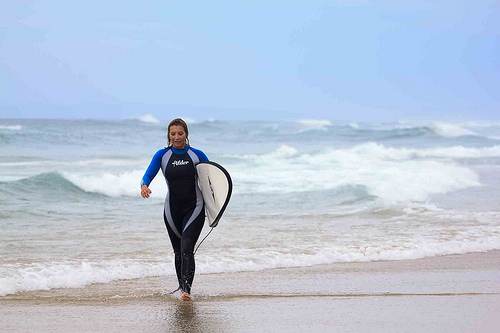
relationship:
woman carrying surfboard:
[140, 117, 209, 301] [192, 154, 233, 228]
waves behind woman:
[219, 108, 476, 213] [140, 117, 209, 301]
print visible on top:
[167, 157, 193, 170] [139, 146, 209, 295]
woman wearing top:
[140, 117, 209, 301] [139, 146, 209, 295]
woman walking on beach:
[140, 117, 209, 301] [1, 248, 498, 331]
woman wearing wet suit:
[140, 117, 209, 301] [141, 149, 211, 289]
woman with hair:
[140, 117, 209, 301] [165, 118, 189, 146]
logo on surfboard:
[199, 167, 234, 201] [179, 147, 240, 215]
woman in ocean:
[140, 117, 209, 301] [1, 114, 498, 301]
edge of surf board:
[198, 161, 234, 226] [195, 153, 235, 232]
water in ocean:
[0, 112, 499, 296] [1, 114, 498, 301]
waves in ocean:
[0, 112, 499, 295] [1, 114, 498, 301]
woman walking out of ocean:
[143, 113, 206, 301] [1, 114, 498, 301]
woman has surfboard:
[140, 117, 209, 301] [196, 160, 233, 227]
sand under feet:
[1, 247, 498, 330] [173, 290, 196, 305]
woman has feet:
[140, 117, 209, 301] [173, 290, 196, 305]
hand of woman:
[138, 185, 153, 199] [140, 117, 209, 301]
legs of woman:
[161, 207, 185, 297] [140, 117, 209, 301]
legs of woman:
[177, 207, 203, 298] [140, 117, 209, 301]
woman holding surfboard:
[140, 117, 209, 301] [192, 152, 240, 229]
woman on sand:
[140, 117, 209, 301] [148, 285, 215, 312]